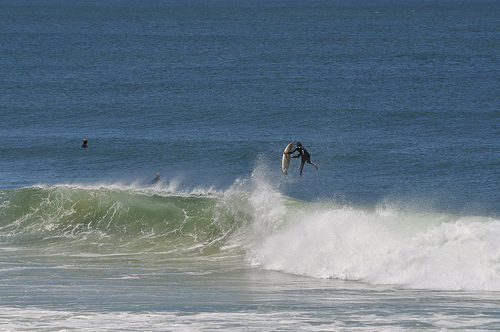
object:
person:
[283, 142, 318, 178]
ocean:
[0, 0, 500, 332]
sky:
[0, 0, 500, 332]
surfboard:
[282, 142, 294, 176]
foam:
[0, 185, 500, 330]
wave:
[0, 186, 500, 292]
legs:
[300, 159, 306, 176]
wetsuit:
[286, 146, 314, 175]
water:
[0, 0, 500, 332]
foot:
[314, 164, 319, 170]